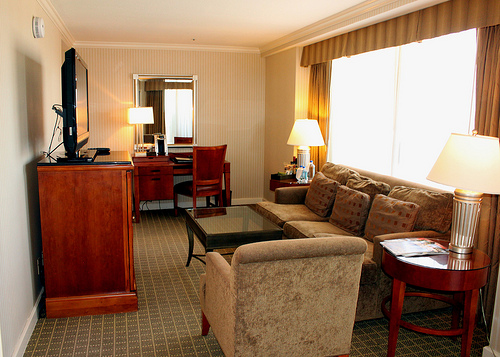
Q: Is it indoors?
A: Yes, it is indoors.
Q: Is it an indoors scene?
A: Yes, it is indoors.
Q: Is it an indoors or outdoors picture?
A: It is indoors.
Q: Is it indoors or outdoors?
A: It is indoors.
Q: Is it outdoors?
A: No, it is indoors.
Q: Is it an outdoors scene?
A: No, it is indoors.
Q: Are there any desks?
A: Yes, there is a desk.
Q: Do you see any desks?
A: Yes, there is a desk.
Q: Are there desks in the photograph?
A: Yes, there is a desk.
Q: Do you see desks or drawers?
A: Yes, there is a desk.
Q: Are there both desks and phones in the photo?
A: No, there is a desk but no phones.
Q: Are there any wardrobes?
A: No, there are no wardrobes.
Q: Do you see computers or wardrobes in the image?
A: No, there are no wardrobes or computers.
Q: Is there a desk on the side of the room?
A: Yes, there is a desk on the side of the room.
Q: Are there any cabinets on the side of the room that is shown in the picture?
A: No, there is a desk on the side of the room.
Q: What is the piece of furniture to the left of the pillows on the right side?
A: The piece of furniture is a desk.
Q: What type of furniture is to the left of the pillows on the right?
A: The piece of furniture is a desk.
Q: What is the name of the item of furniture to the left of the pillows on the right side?
A: The piece of furniture is a desk.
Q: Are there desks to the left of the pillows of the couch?
A: Yes, there is a desk to the left of the pillows.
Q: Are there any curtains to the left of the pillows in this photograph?
A: No, there is a desk to the left of the pillows.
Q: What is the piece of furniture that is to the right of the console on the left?
A: The piece of furniture is a desk.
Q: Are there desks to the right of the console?
A: Yes, there is a desk to the right of the console.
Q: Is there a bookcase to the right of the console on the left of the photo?
A: No, there is a desk to the right of the console.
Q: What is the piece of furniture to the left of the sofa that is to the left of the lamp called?
A: The piece of furniture is a desk.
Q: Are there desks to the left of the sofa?
A: Yes, there is a desk to the left of the sofa.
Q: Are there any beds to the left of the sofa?
A: No, there is a desk to the left of the sofa.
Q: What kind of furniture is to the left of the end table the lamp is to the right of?
A: The piece of furniture is a desk.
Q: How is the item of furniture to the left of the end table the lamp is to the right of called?
A: The piece of furniture is a desk.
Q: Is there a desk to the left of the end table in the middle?
A: Yes, there is a desk to the left of the end table.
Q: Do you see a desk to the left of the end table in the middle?
A: Yes, there is a desk to the left of the end table.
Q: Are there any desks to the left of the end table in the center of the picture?
A: Yes, there is a desk to the left of the end table.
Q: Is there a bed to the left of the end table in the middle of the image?
A: No, there is a desk to the left of the end table.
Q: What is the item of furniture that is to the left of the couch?
A: The piece of furniture is a desk.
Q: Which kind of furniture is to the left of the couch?
A: The piece of furniture is a desk.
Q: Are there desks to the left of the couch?
A: Yes, there is a desk to the left of the couch.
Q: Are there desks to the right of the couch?
A: No, the desk is to the left of the couch.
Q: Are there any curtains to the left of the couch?
A: No, there is a desk to the left of the couch.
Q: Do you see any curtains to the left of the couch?
A: No, there is a desk to the left of the couch.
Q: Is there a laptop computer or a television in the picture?
A: Yes, there is a television.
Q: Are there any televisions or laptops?
A: Yes, there is a television.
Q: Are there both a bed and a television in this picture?
A: No, there is a television but no beds.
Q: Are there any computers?
A: No, there are no computers.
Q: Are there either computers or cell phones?
A: No, there are no computers or cell phones.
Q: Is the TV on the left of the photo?
A: Yes, the TV is on the left of the image.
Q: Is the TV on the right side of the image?
A: No, the TV is on the left of the image.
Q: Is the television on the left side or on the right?
A: The television is on the left of the image.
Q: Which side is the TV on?
A: The TV is on the left of the image.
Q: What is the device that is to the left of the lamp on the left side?
A: The device is a television.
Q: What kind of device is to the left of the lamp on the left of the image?
A: The device is a television.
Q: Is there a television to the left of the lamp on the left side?
A: Yes, there is a television to the left of the lamp.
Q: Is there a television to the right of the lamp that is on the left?
A: No, the television is to the left of the lamp.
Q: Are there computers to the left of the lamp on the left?
A: No, there is a television to the left of the lamp.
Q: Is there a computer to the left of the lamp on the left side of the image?
A: No, there is a television to the left of the lamp.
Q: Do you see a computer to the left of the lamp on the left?
A: No, there is a television to the left of the lamp.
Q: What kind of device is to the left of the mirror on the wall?
A: The device is a television.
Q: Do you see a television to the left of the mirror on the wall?
A: Yes, there is a television to the left of the mirror.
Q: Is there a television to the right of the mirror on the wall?
A: No, the television is to the left of the mirror.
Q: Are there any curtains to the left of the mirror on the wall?
A: No, there is a television to the left of the mirror.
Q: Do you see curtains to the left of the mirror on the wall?
A: No, there is a television to the left of the mirror.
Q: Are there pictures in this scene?
A: No, there are no pictures.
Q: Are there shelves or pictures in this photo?
A: No, there are no pictures or shelves.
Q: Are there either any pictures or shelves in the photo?
A: No, there are no pictures or shelves.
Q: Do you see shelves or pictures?
A: No, there are no pictures or shelves.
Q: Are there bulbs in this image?
A: No, there are no bulbs.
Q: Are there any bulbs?
A: No, there are no bulbs.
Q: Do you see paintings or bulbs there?
A: No, there are no bulbs or paintings.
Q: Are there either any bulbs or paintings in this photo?
A: No, there are no bulbs or paintings.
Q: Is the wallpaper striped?
A: Yes, the wallpaper is striped.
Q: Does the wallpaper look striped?
A: Yes, the wallpaper is striped.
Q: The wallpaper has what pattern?
A: The wallpaper is striped.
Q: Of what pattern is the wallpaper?
A: The wallpaper is striped.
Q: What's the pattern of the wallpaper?
A: The wallpaper is striped.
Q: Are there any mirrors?
A: Yes, there is a mirror.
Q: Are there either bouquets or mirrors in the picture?
A: Yes, there is a mirror.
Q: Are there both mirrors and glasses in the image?
A: No, there is a mirror but no glasses.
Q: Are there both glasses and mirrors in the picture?
A: No, there is a mirror but no glasses.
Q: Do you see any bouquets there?
A: No, there are no bouquets.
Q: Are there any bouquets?
A: No, there are no bouquets.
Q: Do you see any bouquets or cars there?
A: No, there are no bouquets or cars.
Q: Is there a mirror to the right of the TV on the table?
A: Yes, there is a mirror to the right of the television.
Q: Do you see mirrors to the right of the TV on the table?
A: Yes, there is a mirror to the right of the television.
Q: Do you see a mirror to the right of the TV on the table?
A: Yes, there is a mirror to the right of the television.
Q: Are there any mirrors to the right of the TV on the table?
A: Yes, there is a mirror to the right of the television.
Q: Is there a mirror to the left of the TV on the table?
A: No, the mirror is to the right of the TV.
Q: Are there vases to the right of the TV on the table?
A: No, there is a mirror to the right of the television.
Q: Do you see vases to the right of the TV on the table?
A: No, there is a mirror to the right of the television.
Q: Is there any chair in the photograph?
A: Yes, there is a chair.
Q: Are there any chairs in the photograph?
A: Yes, there is a chair.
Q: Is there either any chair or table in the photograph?
A: Yes, there is a chair.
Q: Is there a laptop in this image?
A: No, there are no laptops.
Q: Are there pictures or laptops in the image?
A: No, there are no laptops or pictures.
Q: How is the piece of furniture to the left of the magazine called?
A: The piece of furniture is a chair.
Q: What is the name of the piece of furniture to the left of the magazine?
A: The piece of furniture is a chair.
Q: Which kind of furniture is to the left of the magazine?
A: The piece of furniture is a chair.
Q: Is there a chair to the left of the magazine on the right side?
A: Yes, there is a chair to the left of the magazine.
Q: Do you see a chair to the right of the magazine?
A: No, the chair is to the left of the magazine.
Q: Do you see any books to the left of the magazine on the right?
A: No, there is a chair to the left of the magazine.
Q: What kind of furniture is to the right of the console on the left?
A: The piece of furniture is a chair.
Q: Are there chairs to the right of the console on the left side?
A: Yes, there is a chair to the right of the console.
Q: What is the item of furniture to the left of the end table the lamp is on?
A: The piece of furniture is a chair.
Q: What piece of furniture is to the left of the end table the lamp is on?
A: The piece of furniture is a chair.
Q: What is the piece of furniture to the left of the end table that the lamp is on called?
A: The piece of furniture is a chair.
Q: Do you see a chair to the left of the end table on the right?
A: Yes, there is a chair to the left of the end table.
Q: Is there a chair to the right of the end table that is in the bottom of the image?
A: No, the chair is to the left of the end table.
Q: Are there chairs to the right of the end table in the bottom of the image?
A: No, the chair is to the left of the end table.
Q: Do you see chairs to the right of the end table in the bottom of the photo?
A: No, the chair is to the left of the end table.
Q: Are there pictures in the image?
A: No, there are no pictures.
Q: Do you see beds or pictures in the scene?
A: No, there are no pictures or beds.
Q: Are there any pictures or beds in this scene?
A: No, there are no pictures or beds.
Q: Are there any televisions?
A: Yes, there is a television.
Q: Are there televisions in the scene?
A: Yes, there is a television.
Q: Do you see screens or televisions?
A: Yes, there is a television.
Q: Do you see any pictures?
A: No, there are no pictures.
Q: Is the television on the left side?
A: Yes, the television is on the left of the image.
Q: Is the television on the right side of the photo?
A: No, the television is on the left of the image.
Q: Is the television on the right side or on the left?
A: The television is on the left of the image.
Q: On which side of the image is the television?
A: The television is on the left of the image.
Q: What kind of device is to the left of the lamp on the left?
A: The device is a television.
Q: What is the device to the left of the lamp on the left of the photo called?
A: The device is a television.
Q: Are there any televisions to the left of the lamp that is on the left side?
A: Yes, there is a television to the left of the lamp.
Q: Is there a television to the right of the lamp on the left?
A: No, the television is to the left of the lamp.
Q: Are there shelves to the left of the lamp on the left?
A: No, there is a television to the left of the lamp.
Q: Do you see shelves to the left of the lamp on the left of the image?
A: No, there is a television to the left of the lamp.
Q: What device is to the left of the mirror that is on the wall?
A: The device is a television.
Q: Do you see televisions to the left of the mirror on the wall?
A: Yes, there is a television to the left of the mirror.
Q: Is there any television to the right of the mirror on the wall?
A: No, the television is to the left of the mirror.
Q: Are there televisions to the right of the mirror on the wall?
A: No, the television is to the left of the mirror.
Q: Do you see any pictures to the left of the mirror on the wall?
A: No, there is a television to the left of the mirror.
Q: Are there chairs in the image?
A: Yes, there is a chair.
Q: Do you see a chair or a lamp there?
A: Yes, there is a chair.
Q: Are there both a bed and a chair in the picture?
A: No, there is a chair but no beds.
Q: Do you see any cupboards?
A: No, there are no cupboards.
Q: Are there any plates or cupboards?
A: No, there are no cupboards or plates.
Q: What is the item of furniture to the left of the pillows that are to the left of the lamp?
A: The piece of furniture is a chair.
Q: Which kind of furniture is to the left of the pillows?
A: The piece of furniture is a chair.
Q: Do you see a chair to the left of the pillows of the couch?
A: Yes, there is a chair to the left of the pillows.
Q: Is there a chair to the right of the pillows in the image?
A: No, the chair is to the left of the pillows.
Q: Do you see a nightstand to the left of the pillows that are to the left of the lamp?
A: No, there is a chair to the left of the pillows.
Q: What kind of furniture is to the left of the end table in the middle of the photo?
A: The piece of furniture is a chair.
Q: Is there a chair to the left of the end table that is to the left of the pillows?
A: Yes, there is a chair to the left of the end table.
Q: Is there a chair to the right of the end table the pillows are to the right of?
A: No, the chair is to the left of the end table.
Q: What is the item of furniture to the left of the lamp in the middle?
A: The piece of furniture is a chair.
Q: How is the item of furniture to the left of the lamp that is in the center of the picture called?
A: The piece of furniture is a chair.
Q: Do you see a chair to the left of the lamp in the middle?
A: Yes, there is a chair to the left of the lamp.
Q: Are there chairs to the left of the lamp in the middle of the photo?
A: Yes, there is a chair to the left of the lamp.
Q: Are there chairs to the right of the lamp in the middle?
A: No, the chair is to the left of the lamp.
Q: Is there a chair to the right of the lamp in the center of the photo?
A: No, the chair is to the left of the lamp.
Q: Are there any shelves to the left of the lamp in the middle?
A: No, there is a chair to the left of the lamp.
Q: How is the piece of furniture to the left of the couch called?
A: The piece of furniture is a chair.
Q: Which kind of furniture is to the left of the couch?
A: The piece of furniture is a chair.